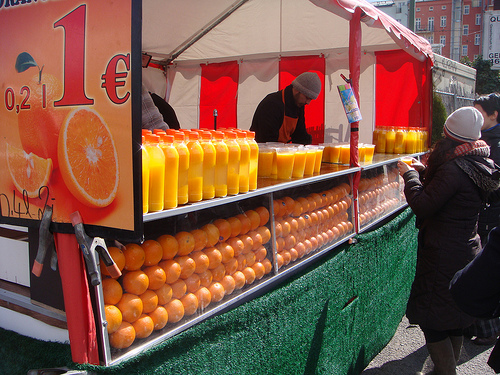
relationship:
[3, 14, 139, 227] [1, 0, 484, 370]
advertisement on side of shop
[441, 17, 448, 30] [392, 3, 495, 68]
window in building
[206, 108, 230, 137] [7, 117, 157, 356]
handle of door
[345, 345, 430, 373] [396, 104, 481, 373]
shadow of person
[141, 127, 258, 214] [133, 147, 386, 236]
bottle on counter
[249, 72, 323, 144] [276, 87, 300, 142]
man wearing apron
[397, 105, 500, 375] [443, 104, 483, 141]
person wearing stocking cap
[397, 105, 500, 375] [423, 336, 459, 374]
person wearing boot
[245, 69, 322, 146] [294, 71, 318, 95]
man wearing beanie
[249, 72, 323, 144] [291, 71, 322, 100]
man wearing beanie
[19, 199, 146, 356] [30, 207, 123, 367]
clamps securing clamps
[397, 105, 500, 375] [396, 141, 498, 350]
person wearing coat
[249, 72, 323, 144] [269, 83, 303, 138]
man wearing apron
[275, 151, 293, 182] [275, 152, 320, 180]
glasses of orange juice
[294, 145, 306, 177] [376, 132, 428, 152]
glasses of orange juice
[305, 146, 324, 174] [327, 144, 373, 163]
glasses of orange juice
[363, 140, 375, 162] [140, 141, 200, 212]
glasses of orange juice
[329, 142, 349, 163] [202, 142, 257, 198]
glasses of orange juice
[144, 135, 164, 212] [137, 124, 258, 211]
bottle of orange juice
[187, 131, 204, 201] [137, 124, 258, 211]
bottle of orange juice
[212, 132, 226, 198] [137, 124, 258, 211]
bottle of orange juice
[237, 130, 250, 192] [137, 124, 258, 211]
bottle of orange juice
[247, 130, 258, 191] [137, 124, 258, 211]
bottle of orange juice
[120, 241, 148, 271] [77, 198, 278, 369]
orange on display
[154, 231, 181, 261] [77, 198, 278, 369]
orange on display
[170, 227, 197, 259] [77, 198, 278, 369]
orange on display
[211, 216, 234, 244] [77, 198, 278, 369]
orange on display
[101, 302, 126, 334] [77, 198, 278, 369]
orange on display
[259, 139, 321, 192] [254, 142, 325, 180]
glasses on glasses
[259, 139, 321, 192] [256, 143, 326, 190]
glasses of juice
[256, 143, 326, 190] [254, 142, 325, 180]
juice on glasses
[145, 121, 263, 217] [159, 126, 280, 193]
bottle of orange juice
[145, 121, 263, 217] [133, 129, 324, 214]
bottle on display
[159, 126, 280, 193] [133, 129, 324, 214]
orange juice on display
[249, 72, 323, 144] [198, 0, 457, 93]
man under tent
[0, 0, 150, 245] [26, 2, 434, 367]
advertisement on booth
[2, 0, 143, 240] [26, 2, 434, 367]
banner on booth